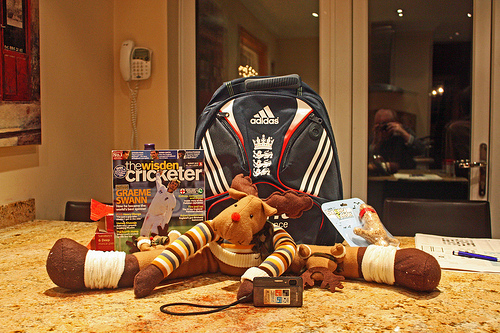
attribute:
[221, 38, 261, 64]
window — part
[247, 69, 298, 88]
handle — part, grey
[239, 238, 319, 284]
doll — part, edge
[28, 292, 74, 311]
table — part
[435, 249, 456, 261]
paper — part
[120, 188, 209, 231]
book — part, edge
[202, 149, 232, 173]
camera — part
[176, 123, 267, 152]
bag — edge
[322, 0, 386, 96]
door — edge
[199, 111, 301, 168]
backpack — black, adidas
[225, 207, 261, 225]
animal — stuffed, reindeer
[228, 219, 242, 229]
nose — red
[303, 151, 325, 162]
lines — white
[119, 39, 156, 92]
phone — white, part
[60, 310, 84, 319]
counter — tan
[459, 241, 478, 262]
pen — blue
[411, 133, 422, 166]
arm — part